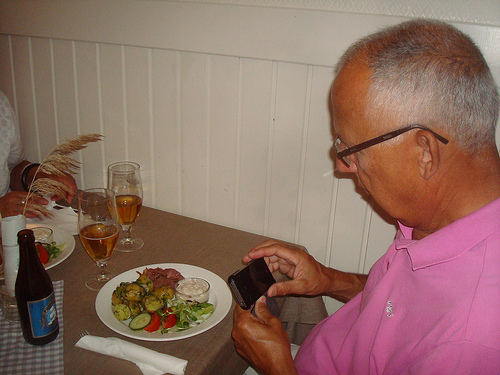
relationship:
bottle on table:
[9, 221, 75, 342] [3, 185, 321, 370]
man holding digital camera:
[307, 17, 490, 369] [229, 243, 276, 304]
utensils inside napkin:
[75, 328, 91, 342] [79, 335, 184, 374]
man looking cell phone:
[307, 17, 500, 375] [227, 256, 281, 309]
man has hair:
[307, 17, 500, 375] [331, 18, 499, 159]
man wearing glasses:
[307, 17, 500, 375] [334, 123, 449, 166]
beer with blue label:
[13, 227, 61, 346] [22, 288, 64, 340]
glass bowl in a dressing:
[174, 275, 211, 305] [175, 275, 212, 303]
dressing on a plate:
[175, 275, 212, 303] [96, 261, 233, 343]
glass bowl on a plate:
[174, 275, 211, 305] [96, 261, 233, 343]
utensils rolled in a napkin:
[75, 328, 91, 342] [79, 335, 184, 374]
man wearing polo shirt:
[307, 17, 500, 375] [291, 195, 499, 375]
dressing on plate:
[175, 275, 212, 303] [96, 261, 233, 343]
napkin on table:
[73, 332, 189, 374] [0, 162, 309, 374]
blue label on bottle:
[22, 297, 62, 340] [7, 223, 59, 348]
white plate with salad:
[91, 262, 234, 342] [108, 265, 218, 336]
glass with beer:
[78, 186, 121, 291] [77, 221, 119, 259]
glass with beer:
[108, 162, 144, 252] [109, 191, 141, 224]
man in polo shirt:
[307, 17, 500, 375] [291, 195, 497, 372]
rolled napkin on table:
[60, 338, 194, 373] [0, 162, 309, 374]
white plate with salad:
[91, 262, 234, 342] [133, 293, 218, 338]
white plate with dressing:
[91, 262, 234, 342] [175, 275, 212, 303]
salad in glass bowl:
[133, 293, 218, 338] [176, 275, 211, 305]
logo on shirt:
[384, 304, 395, 321] [308, 237, 496, 374]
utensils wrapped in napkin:
[75, 328, 91, 342] [73, 332, 189, 374]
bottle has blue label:
[9, 221, 75, 342] [22, 288, 64, 340]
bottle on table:
[9, 221, 75, 342] [3, 137, 317, 373]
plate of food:
[96, 261, 233, 343] [111, 265, 215, 333]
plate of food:
[0, 222, 78, 280] [30, 222, 69, 264]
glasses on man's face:
[332, 127, 453, 170] [323, 64, 423, 234]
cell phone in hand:
[237, 236, 272, 303] [227, 289, 298, 373]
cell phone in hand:
[237, 236, 272, 303] [242, 239, 331, 302]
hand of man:
[227, 289, 298, 373] [307, 17, 500, 375]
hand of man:
[242, 239, 331, 302] [307, 17, 500, 375]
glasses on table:
[69, 189, 134, 276] [166, 231, 218, 257]